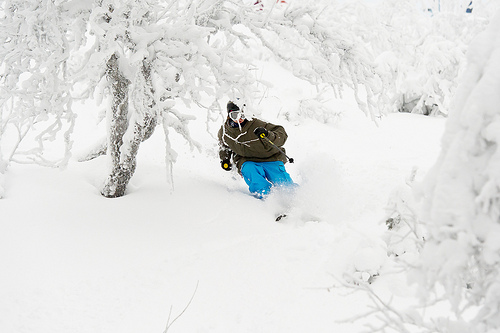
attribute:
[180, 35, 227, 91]
snow — soft, clean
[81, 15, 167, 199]
tree — snowy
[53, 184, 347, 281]
snow — kicked up, flying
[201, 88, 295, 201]
man — skiing, kicking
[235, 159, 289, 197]
pants — blue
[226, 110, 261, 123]
goggles — protecting, white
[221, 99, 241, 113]
hat — knit, warm, pointy, black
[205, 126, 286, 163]
jacket — brown, green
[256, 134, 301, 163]
pole — yellow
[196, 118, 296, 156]
coat — brown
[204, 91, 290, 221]
man — skiing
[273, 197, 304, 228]
skis — yellow